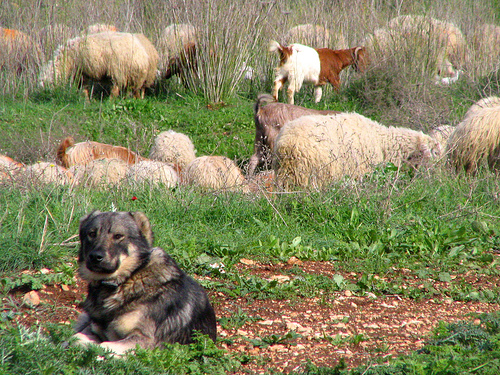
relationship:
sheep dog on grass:
[74, 220, 213, 349] [385, 236, 472, 252]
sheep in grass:
[35, 35, 208, 90] [385, 236, 472, 252]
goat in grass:
[253, 51, 368, 96] [385, 236, 472, 252]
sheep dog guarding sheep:
[74, 220, 213, 349] [35, 35, 208, 90]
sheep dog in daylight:
[74, 220, 213, 349] [346, 4, 369, 9]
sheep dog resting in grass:
[74, 220, 213, 349] [385, 236, 472, 252]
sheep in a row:
[7, 147, 247, 194] [22, 137, 76, 184]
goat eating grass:
[253, 51, 368, 96] [385, 236, 472, 252]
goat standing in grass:
[253, 51, 368, 96] [385, 236, 472, 252]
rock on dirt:
[12, 269, 48, 325] [282, 303, 379, 319]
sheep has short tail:
[35, 35, 208, 90] [142, 41, 158, 66]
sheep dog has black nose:
[74, 220, 213, 349] [87, 242, 112, 265]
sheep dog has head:
[74, 220, 213, 349] [69, 208, 168, 279]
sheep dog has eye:
[74, 220, 213, 349] [113, 223, 149, 254]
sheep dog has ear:
[74, 220, 213, 349] [131, 209, 157, 238]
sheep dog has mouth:
[74, 220, 213, 349] [79, 262, 129, 275]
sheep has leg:
[35, 35, 208, 90] [105, 79, 133, 106]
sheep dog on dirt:
[74, 220, 213, 349] [282, 303, 379, 319]